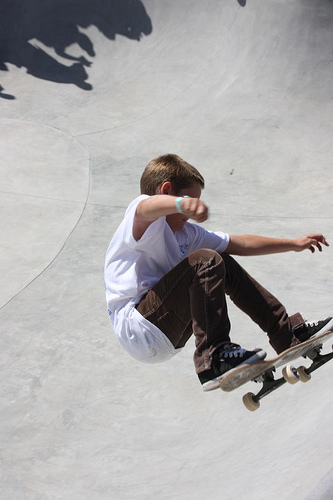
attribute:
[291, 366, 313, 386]
wheel — white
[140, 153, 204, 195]
hair — brown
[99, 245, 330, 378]
pants — brown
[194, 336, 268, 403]
shoe — black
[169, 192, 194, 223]
blue band — thin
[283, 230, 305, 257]
wrist — small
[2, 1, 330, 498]
ground — gray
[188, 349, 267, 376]
shoes — black, white, skater's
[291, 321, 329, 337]
shoes — white, black, skater's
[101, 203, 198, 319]
t-shirt — White 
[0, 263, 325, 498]
ground — gray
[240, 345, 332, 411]
wheels — white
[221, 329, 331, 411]
skateboard — white, black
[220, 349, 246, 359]
laces — White 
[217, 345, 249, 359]
shoelaces — white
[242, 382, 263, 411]
wheel — white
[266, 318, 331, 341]
shoe — black, white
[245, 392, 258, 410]
wheel — white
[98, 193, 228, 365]
t-shirt — white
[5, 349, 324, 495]
ground — cement